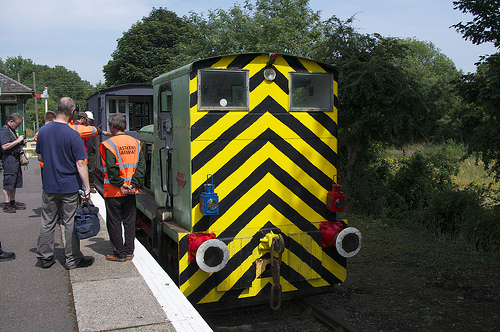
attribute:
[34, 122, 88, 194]
shirt — blue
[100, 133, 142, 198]
vest — safety, orange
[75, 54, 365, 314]
train — small, green, black, yellow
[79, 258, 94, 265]
shoe — black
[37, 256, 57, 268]
shoe — black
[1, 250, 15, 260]
shoe — black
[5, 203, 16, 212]
shoe — black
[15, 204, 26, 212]
shoe — black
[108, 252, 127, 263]
shoe — brown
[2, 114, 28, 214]
man — standing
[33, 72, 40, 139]
pole — wooden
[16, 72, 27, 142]
pole — wooden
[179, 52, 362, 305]
back — black, yellow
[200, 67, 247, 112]
window — square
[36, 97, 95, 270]
man — balding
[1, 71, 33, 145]
building — green, white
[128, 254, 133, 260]
shoe — leather, orange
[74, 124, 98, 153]
vest — safety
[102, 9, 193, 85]
tree — tall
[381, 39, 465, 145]
tree — green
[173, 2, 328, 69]
tree — tall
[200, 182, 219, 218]
lantern — blue